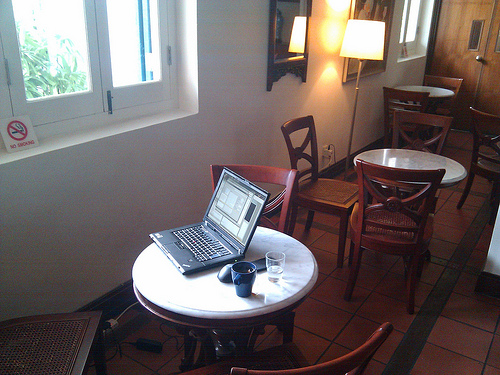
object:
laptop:
[148, 166, 272, 276]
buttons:
[201, 259, 205, 262]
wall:
[0, 0, 438, 327]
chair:
[343, 156, 447, 315]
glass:
[264, 251, 286, 284]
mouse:
[217, 263, 234, 284]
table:
[131, 224, 319, 375]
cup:
[231, 261, 256, 302]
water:
[268, 265, 283, 284]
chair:
[178, 317, 395, 375]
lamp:
[338, 18, 386, 183]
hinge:
[167, 45, 173, 64]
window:
[93, 0, 173, 115]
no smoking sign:
[1, 115, 39, 154]